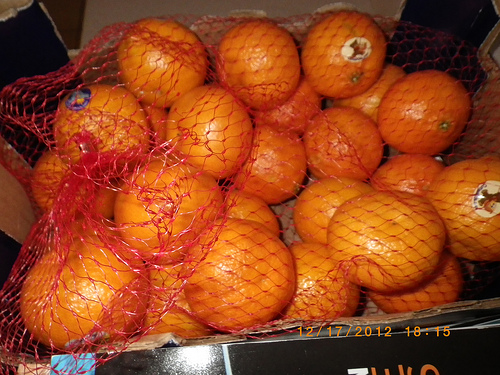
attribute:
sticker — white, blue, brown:
[350, 41, 373, 65]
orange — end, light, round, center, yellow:
[222, 30, 309, 101]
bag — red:
[4, 84, 59, 114]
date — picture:
[289, 323, 394, 336]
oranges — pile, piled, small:
[128, 94, 379, 242]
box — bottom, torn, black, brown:
[166, 357, 307, 367]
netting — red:
[43, 66, 65, 79]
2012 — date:
[350, 321, 398, 341]